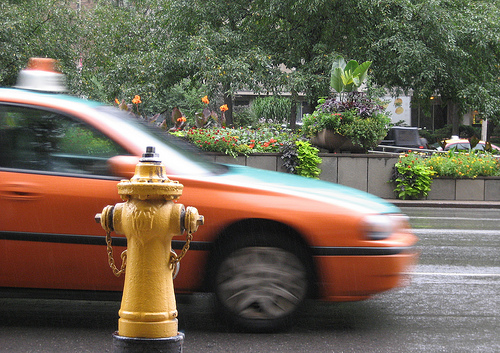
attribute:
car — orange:
[0, 82, 417, 329]